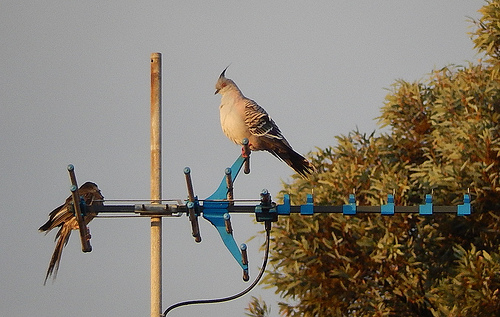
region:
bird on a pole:
[150, 47, 317, 255]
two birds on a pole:
[43, 30, 324, 286]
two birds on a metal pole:
[3, 58, 430, 308]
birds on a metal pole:
[5, 81, 300, 315]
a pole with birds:
[14, 8, 321, 313]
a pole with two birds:
[27, 44, 382, 287]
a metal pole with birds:
[48, 55, 379, 294]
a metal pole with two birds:
[25, 70, 388, 310]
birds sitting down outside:
[39, 65, 364, 315]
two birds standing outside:
[19, 36, 266, 310]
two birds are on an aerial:
[23, 38, 389, 279]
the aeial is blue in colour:
[165, 117, 495, 278]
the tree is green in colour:
[302, 237, 437, 314]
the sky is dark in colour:
[189, 19, 329, 51]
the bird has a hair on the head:
[205, 53, 234, 79]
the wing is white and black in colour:
[226, 78, 293, 137]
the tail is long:
[39, 193, 86, 275]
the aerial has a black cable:
[251, 222, 278, 295]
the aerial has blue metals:
[282, 185, 475, 222]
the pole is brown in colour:
[131, 41, 175, 314]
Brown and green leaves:
[450, 90, 497, 184]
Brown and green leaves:
[467, 6, 495, 112]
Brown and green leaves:
[431, 242, 481, 309]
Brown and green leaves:
[270, 249, 379, 312]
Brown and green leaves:
[315, 149, 400, 202]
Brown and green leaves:
[377, 71, 496, 183]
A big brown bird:
[188, 66, 318, 231]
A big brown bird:
[43, 158, 109, 252]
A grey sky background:
[25, 15, 160, 165]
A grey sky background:
[265, 20, 345, 77]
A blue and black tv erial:
[119, 26, 486, 263]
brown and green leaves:
[304, 145, 396, 297]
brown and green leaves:
[418, 237, 497, 287]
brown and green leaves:
[383, 81, 491, 171]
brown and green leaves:
[285, 270, 390, 312]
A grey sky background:
[0, 255, 130, 314]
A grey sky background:
[169, 246, 231, 304]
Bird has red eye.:
[216, 78, 233, 91]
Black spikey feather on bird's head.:
[209, 60, 242, 91]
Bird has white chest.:
[211, 105, 241, 149]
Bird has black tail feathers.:
[278, 145, 310, 185]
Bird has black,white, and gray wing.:
[256, 121, 285, 151]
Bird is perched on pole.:
[222, 125, 269, 195]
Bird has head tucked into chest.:
[74, 174, 107, 212]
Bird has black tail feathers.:
[27, 243, 79, 282]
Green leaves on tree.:
[346, 148, 440, 193]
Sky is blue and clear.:
[33, 23, 105, 98]